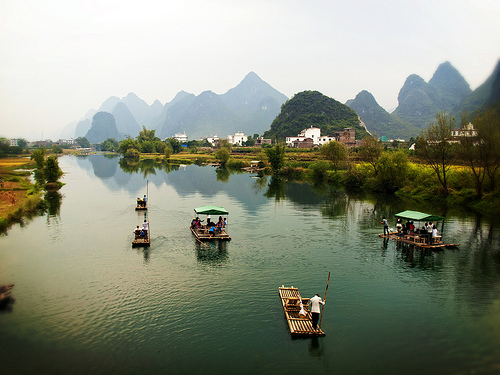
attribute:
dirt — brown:
[1, 178, 31, 209]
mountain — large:
[262, 92, 369, 141]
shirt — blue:
[380, 218, 390, 226]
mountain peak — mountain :
[425, 56, 475, 104]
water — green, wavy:
[6, 147, 497, 372]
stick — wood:
[139, 171, 154, 210]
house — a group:
[295, 140, 315, 149]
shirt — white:
[291, 287, 331, 317]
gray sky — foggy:
[3, 0, 499, 140]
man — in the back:
[301, 290, 326, 335]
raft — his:
[277, 281, 327, 342]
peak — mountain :
[237, 65, 268, 85]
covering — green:
[192, 200, 229, 220]